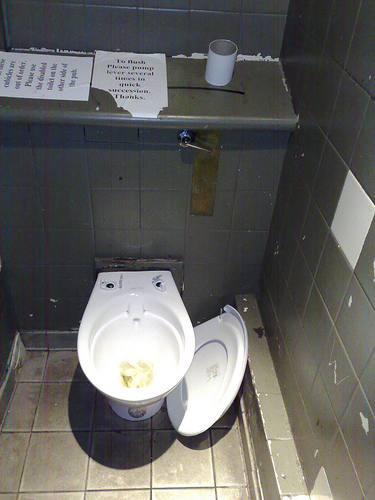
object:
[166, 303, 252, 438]
lid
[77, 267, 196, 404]
toilet seat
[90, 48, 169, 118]
white paper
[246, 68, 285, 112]
ledge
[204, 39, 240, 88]
silver rail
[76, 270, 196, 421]
toilet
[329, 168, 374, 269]
white tile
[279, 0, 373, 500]
wall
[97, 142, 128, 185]
tile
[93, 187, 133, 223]
tile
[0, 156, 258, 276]
wall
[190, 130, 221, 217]
board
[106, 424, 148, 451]
shadow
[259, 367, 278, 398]
ledge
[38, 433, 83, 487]
floor